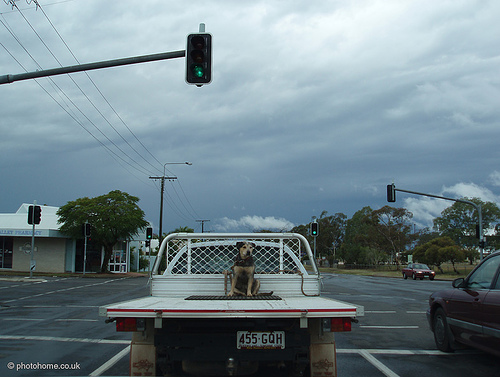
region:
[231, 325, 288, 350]
White license plate with black numbers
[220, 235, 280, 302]
Dog sitting in the back of a truck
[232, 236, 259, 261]
Black and brown dog head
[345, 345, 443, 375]
White stripes on the road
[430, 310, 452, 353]
Left front tire of a car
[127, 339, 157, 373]
White mud flap with red letters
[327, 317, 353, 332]
Red tail light on back of truck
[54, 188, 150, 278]
Two dark green trees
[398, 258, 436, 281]
Red car with the headlights on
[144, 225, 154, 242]
Traffic light with green signal on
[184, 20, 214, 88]
Traffic light with green signal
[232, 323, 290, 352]
White license plate with black letters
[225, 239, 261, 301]
Black and brown dog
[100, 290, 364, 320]
White flat bed with red stripe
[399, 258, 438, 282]
Red car with headlights on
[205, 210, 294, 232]
White cloud in the sky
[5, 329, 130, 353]
White stripe on the road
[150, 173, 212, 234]
Two telephone poles with wires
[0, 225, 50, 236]
White sign with blue letters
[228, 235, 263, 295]
a dog sitting on the bed of a flat bed truck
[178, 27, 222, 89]
a traffic that is green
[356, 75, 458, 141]
clouds in the sky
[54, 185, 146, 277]
a tree by a building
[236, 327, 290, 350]
a license plate on a truck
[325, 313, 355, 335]
the tail light of a truck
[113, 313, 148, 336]
the tail light of a truck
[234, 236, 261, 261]
the head of a dog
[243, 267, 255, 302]
the leg of a dog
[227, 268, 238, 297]
the leg of a dog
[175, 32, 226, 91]
traffic light shows green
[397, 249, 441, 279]
car stopped at traffic light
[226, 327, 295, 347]
license plate of vehicle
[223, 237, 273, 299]
dog sitting down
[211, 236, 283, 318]
dog sitting down on truck bed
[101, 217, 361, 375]
truck going through an intersection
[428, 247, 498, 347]
partial view of a vehicle going through the intersection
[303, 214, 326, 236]
traffic light shows green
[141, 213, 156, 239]
traffic light shows green green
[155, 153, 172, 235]
telephone pole in the distance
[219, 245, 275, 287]
dog on back of trailer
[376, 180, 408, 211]
traffic light on pole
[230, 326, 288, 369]
license plate on back of truck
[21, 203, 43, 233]
traffic light on pole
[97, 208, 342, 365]
truck on the road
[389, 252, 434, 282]
vehicle on the road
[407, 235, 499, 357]
vehicle on the road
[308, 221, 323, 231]
traffic light on a pole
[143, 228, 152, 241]
traffic light on a pole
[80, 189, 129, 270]
tree on side of road